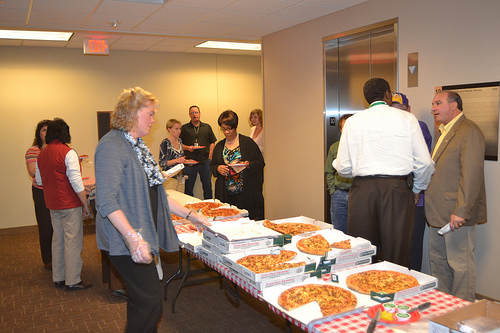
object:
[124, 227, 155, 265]
glove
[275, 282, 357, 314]
pizza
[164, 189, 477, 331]
table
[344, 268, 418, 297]
pizza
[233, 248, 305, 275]
pizza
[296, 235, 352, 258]
pizza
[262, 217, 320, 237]
pizza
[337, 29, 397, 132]
elevator doors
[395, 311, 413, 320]
sauce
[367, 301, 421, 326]
plate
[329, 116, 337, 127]
floor number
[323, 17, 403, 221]
elevator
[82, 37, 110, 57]
exit sign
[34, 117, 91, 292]
woman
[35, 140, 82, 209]
vest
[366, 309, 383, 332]
knife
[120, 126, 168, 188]
scarf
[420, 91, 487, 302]
man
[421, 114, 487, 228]
sport coat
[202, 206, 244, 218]
pizza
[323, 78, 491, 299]
group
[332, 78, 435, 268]
man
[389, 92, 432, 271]
man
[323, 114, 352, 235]
man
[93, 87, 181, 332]
woman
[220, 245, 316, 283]
box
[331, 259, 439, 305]
box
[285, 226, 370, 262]
box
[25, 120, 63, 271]
woman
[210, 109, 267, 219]
woman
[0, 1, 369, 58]
ceiling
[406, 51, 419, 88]
sign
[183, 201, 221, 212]
pizza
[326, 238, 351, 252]
slice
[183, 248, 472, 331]
tablecloth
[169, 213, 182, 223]
pizzas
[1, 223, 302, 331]
floor